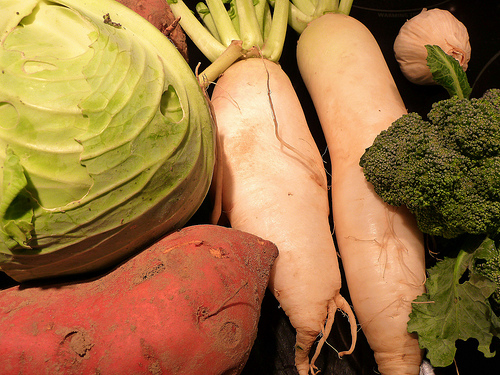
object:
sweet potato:
[1, 224, 278, 374]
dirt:
[70, 330, 92, 355]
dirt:
[148, 361, 163, 373]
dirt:
[98, 348, 109, 362]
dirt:
[188, 352, 205, 366]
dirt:
[254, 268, 268, 285]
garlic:
[389, 6, 474, 91]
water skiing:
[431, 213, 493, 240]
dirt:
[130, 263, 148, 281]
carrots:
[294, 0, 442, 373]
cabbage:
[6, 10, 227, 265]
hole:
[150, 74, 202, 121]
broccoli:
[366, 84, 485, 241]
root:
[307, 292, 338, 371]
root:
[333, 285, 358, 361]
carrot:
[167, 0, 357, 372]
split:
[258, 60, 328, 193]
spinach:
[409, 231, 499, 370]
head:
[373, 93, 485, 206]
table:
[0, 0, 499, 373]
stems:
[162, 8, 286, 62]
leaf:
[422, 293, 489, 351]